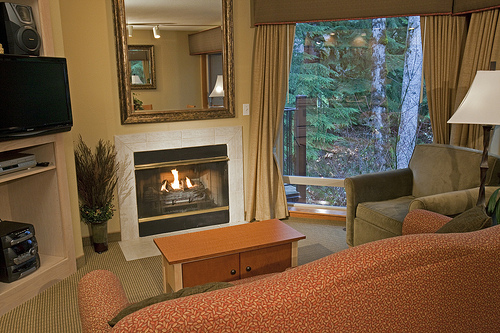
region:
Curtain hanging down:
[244, 25, 291, 218]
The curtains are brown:
[245, 10, 497, 217]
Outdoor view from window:
[284, 17, 432, 204]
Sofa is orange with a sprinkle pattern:
[77, 208, 499, 331]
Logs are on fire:
[151, 164, 205, 211]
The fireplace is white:
[112, 124, 244, 258]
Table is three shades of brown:
[152, 217, 304, 292]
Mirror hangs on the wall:
[112, 0, 235, 122]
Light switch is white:
[240, 102, 250, 116]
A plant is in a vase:
[73, 134, 118, 251]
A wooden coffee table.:
[151, 217, 307, 294]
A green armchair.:
[341, 142, 498, 254]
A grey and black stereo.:
[2, 222, 42, 281]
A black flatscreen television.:
[0, 55, 74, 144]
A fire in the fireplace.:
[144, 159, 225, 219]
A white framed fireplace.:
[111, 125, 256, 260]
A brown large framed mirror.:
[111, 2, 238, 123]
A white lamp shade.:
[447, 70, 499, 124]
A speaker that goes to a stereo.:
[4, 1, 45, 55]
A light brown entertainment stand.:
[1, 137, 78, 317]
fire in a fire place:
[106, 145, 243, 227]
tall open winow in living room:
[246, 59, 420, 211]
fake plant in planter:
[74, 143, 141, 302]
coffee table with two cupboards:
[160, 206, 310, 309]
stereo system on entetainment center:
[2, 205, 62, 272]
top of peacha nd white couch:
[197, 224, 488, 325]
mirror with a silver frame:
[115, 53, 249, 122]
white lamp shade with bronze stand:
[421, 60, 496, 208]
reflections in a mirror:
[107, 56, 229, 133]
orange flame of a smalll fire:
[124, 168, 199, 210]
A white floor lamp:
[445, 41, 498, 207]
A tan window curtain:
[231, 15, 291, 220]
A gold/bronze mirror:
[105, 0, 237, 135]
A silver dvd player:
[0, 145, 36, 175]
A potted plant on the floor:
[70, 130, 125, 251]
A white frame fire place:
[110, 120, 245, 255]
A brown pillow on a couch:
[426, 200, 488, 236]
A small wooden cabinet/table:
[130, 212, 305, 289]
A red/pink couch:
[66, 206, 496, 330]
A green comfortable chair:
[336, 133, 496, 246]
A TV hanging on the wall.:
[0, 51, 92, 136]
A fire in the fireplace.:
[130, 145, 248, 237]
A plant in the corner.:
[78, 137, 119, 263]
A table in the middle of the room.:
[140, 222, 313, 290]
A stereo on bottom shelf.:
[2, 214, 49, 293]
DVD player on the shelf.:
[1, 157, 44, 182]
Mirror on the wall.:
[106, 2, 241, 120]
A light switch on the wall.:
[242, 103, 251, 115]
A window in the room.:
[290, 28, 411, 205]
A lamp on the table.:
[450, 67, 498, 210]